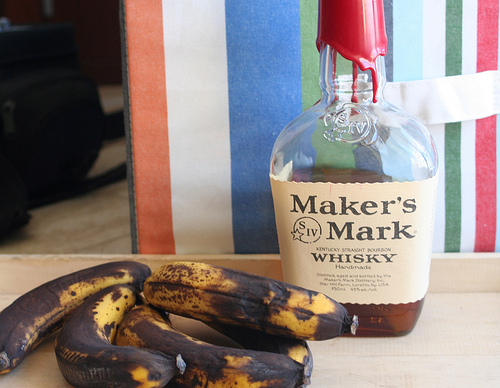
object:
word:
[301, 243, 415, 273]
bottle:
[266, 32, 440, 337]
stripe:
[223, 0, 304, 258]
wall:
[122, 1, 500, 257]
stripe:
[121, 0, 177, 256]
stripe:
[162, 0, 236, 257]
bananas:
[141, 258, 357, 342]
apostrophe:
[396, 194, 405, 204]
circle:
[321, 103, 374, 148]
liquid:
[327, 302, 424, 338]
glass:
[269, 41, 442, 339]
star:
[290, 227, 304, 242]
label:
[277, 192, 421, 296]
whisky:
[351, 304, 416, 337]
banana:
[52, 284, 186, 386]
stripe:
[441, 1, 463, 254]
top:
[314, 0, 389, 72]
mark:
[328, 217, 414, 245]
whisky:
[308, 246, 403, 265]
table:
[0, 251, 500, 387]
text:
[288, 192, 419, 294]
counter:
[263, 259, 500, 386]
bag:
[9, 78, 104, 209]